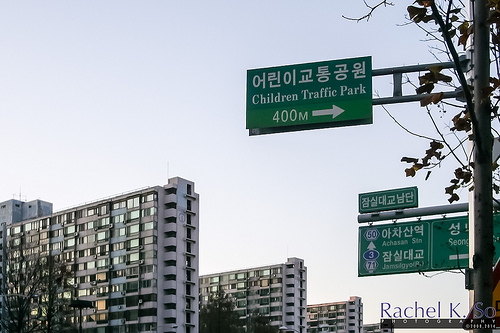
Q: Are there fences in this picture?
A: No, there are no fences.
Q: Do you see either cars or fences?
A: No, there are no fences or cars.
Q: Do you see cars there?
A: No, there are no cars.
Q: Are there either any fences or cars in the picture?
A: No, there are no cars or fences.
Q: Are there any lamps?
A: No, there are no lamps.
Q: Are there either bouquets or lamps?
A: No, there are no lamps or bouquets.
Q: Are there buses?
A: No, there are no buses.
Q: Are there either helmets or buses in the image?
A: No, there are no buses or helmets.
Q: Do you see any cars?
A: No, there are no cars.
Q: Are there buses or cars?
A: No, there are no cars or buses.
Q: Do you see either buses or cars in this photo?
A: No, there are no cars or buses.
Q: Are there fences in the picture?
A: No, there are no fences.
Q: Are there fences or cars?
A: No, there are no fences or cars.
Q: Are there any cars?
A: No, there are no cars.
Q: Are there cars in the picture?
A: No, there are no cars.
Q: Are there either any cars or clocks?
A: No, there are no cars or clocks.